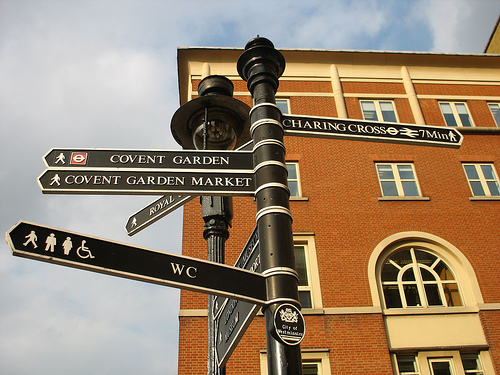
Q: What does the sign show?
A: Where bathrooms are.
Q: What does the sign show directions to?
A: Covent Garden and Covent Garden Market.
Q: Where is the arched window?
A: In the brick building.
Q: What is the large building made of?
A: Red brick.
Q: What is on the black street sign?
A: Symbols.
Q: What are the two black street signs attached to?
A: A post.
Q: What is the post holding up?
A: Street signs.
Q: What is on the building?
A: An arched window.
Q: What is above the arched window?
A: A small square window.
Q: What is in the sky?
A: Clouds.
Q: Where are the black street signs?
A: Attached to a pole.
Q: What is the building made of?
A: Red brick.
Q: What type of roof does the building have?
A: Flat.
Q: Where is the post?
A: In front of the building.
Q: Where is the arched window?
A: On the building.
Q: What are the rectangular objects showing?
A: Windows on front of building.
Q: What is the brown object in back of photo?
A: Large brick building with windows.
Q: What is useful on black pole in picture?
A: The signs are very helpful.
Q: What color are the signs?
A: Black with light letters.